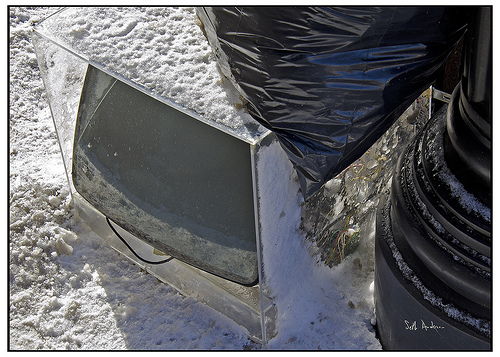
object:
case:
[29, 8, 431, 347]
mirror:
[78, 62, 257, 252]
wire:
[106, 217, 175, 265]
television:
[28, 6, 437, 346]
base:
[373, 91, 491, 353]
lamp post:
[461, 6, 492, 137]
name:
[403, 319, 445, 339]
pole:
[366, 9, 494, 353]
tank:
[372, 76, 493, 353]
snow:
[64, 9, 200, 70]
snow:
[6, 7, 492, 351]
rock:
[10, 99, 78, 349]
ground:
[10, 6, 384, 351]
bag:
[193, 5, 480, 203]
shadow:
[61, 216, 375, 353]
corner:
[287, 158, 357, 189]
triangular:
[253, 98, 442, 352]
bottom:
[374, 289, 498, 352]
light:
[7, 267, 125, 351]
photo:
[8, 6, 493, 353]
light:
[246, 40, 309, 107]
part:
[379, 197, 491, 338]